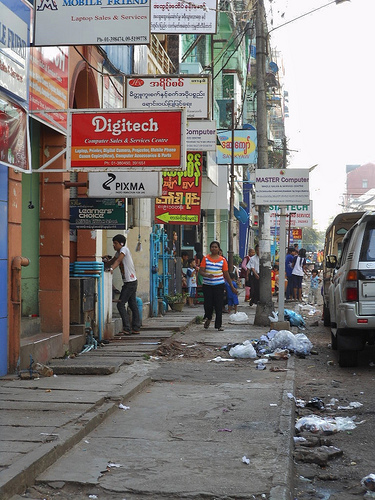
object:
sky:
[263, 0, 374, 233]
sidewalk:
[1, 289, 297, 498]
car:
[325, 209, 374, 368]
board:
[66, 106, 187, 172]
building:
[0, 1, 289, 381]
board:
[123, 73, 212, 122]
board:
[34, 0, 152, 47]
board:
[68, 197, 126, 231]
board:
[154, 150, 203, 225]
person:
[199, 240, 239, 331]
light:
[266, 1, 351, 40]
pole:
[252, 0, 274, 327]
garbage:
[207, 329, 313, 369]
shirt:
[199, 254, 228, 286]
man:
[107, 234, 140, 336]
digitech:
[91, 115, 158, 136]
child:
[310, 268, 323, 304]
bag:
[228, 339, 257, 360]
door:
[20, 118, 41, 317]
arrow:
[155, 212, 199, 223]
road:
[290, 269, 375, 498]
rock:
[293, 442, 342, 465]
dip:
[153, 338, 231, 359]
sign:
[254, 168, 310, 207]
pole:
[278, 205, 287, 322]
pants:
[202, 283, 224, 330]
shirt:
[310, 275, 319, 288]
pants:
[307, 288, 318, 304]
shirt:
[114, 246, 137, 282]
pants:
[117, 278, 141, 332]